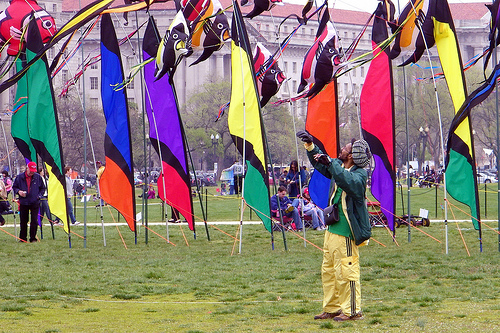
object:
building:
[0, 0, 395, 131]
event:
[0, 0, 499, 332]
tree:
[175, 70, 306, 183]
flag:
[27, 7, 72, 237]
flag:
[97, 8, 138, 237]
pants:
[317, 227, 362, 317]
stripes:
[347, 279, 357, 315]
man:
[11, 160, 47, 244]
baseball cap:
[26, 161, 38, 172]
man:
[294, 130, 374, 323]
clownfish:
[0, 0, 56, 58]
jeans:
[16, 197, 42, 239]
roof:
[53, 0, 393, 29]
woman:
[282, 160, 307, 201]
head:
[288, 160, 299, 173]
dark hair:
[288, 159, 300, 175]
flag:
[141, 15, 195, 232]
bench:
[266, 195, 322, 233]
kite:
[163, 0, 233, 86]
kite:
[328, 0, 429, 81]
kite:
[268, 0, 343, 109]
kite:
[216, 41, 286, 121]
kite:
[0, 0, 57, 78]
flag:
[432, 0, 479, 234]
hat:
[351, 137, 373, 167]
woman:
[290, 186, 330, 232]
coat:
[270, 194, 295, 215]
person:
[268, 184, 306, 231]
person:
[293, 187, 326, 231]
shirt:
[323, 168, 354, 238]